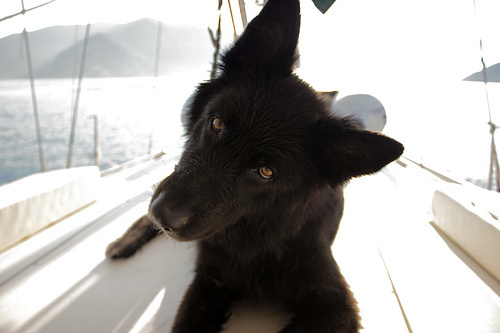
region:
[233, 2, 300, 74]
The left ear of the dog.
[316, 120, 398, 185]
The right ear of the dog.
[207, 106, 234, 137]
The left eye of the dog.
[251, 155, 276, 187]
The right eye of the dog.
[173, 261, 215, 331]
The left leg of the dog.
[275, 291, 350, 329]
The right leg of the dog.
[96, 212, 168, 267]
The back leg of the dog.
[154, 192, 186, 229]
The nose of the dog.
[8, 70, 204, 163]
The water in the distance.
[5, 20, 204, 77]
The mountains in the distance.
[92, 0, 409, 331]
this is a dog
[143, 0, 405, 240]
this is the dog's head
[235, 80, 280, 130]
the fur is black in color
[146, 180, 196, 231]
this is the dog's nose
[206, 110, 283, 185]
these are the dog's eyes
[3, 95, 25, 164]
this is the water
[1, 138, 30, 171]
the water is blue in color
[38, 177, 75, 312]
this is a boat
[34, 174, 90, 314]
the boat is metallic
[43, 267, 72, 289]
the boat is white in color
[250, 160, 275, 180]
this is the eye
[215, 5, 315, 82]
this is the ear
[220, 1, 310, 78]
the ear is big in color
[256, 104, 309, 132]
the fur is black in color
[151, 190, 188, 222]
this is the nose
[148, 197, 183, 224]
the nose is black in color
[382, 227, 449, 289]
this is the boat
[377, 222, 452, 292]
the boat is white in color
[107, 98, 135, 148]
the water is calm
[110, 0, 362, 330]
black dog laying down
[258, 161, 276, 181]
small, round, hazel eye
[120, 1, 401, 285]
dog with its head tilted to the side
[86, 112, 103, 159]
small and skinny pole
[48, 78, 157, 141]
light shining on the water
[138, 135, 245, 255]
black snout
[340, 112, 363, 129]
tuft of black hair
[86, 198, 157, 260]
paw sticking out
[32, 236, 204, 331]
shadows on the floor of the boat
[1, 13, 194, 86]
mountains in the background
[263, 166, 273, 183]
the dog's eye is orange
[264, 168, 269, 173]
the dog's eye is orange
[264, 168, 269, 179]
the dog's eye is orange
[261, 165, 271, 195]
the dog's eye is orange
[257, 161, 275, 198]
the dog's eye is orange